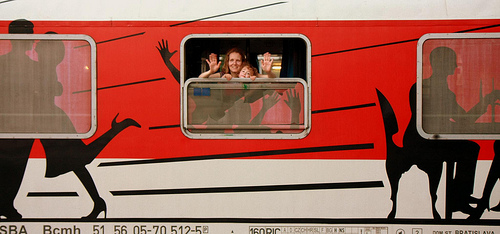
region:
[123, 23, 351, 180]
people sitting in front of window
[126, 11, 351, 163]
people in a window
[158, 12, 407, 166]
an adult and kid in the window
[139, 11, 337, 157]
a child holding onto the window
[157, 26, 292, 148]
a young child holding onto the window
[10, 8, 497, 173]
three windows with a covering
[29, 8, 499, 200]
two windows that are closed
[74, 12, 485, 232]
a window that is open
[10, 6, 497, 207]
three windows in a row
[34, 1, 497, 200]
three windows in row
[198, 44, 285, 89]
woman and child looking out the window of a train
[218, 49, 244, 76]
woman looking out window of train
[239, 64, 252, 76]
child looking out window of train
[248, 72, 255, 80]
childs right hand on window ledge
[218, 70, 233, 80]
childs left hand on window ledge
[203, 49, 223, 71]
womans left hand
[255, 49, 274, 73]
womans right hand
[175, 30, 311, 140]
window of train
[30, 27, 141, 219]
silhouette of woman dancing on side of train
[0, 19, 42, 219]
silhouette of man dancing on side of train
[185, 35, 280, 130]
people in the window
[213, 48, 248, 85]
lady next to the kid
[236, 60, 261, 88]
kid next to the lady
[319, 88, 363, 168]
black lines on the surface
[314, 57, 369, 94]
red background of photo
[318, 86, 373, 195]
red and white wall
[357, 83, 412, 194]
black chair drawn on train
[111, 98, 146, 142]
shoe on the black figure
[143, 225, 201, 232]
numbers on the bottom of the photo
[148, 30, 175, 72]
black hand next to the window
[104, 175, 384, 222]
BLACK AND WHITE AREA ON TRAIN CAR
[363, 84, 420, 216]
CHAIR DRAWING IN BLACK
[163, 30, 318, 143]
PASSENGERS WAVING FROM TRAIN WINDOW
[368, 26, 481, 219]
MAN SITTING IN CHAIR OF ARTWORK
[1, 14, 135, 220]
MAN AND WOMAN DANCING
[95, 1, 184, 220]
ARTWORK ON SIDE OF TRAIN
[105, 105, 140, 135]
PAINTING OF HIGH HEEL SHOE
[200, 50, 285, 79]
WOMANWITH CHILD WAVING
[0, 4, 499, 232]
ARTWORK ON SIDE OF TRAIN CAR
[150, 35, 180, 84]
BLACK HAND WAVING OUT OF WINDOW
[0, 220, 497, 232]
Black lettering under a black line.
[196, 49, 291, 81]
Woman and little girl in window.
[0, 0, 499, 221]
Red and white surface with blacklines and images.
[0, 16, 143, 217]
Image of man and woman kissing behind screen.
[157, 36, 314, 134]
Hands waving on image and woman's hands waving.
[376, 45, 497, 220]
Image of man sitting at table with someone.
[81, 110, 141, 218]
Black high heels are on the feet.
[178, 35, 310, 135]
A rectangular window is open.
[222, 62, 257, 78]
Little girl is holding on to surface.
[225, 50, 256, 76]
The woman and little girl are smiling.